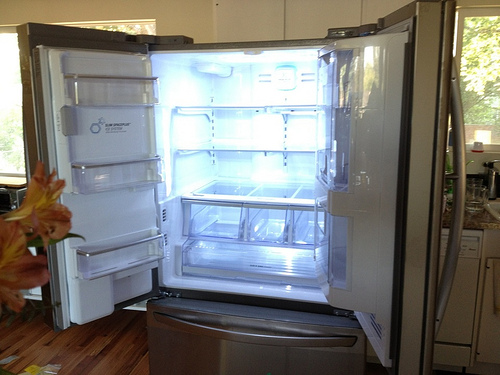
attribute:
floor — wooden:
[1, 308, 145, 374]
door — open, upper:
[15, 21, 165, 331]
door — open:
[314, 0, 466, 375]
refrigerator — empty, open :
[8, 10, 440, 350]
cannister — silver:
[475, 157, 499, 195]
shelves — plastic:
[138, 70, 346, 330]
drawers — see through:
[56, 74, 183, 332]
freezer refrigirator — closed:
[27, 0, 474, 370]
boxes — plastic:
[179, 180, 330, 248]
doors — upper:
[14, 16, 430, 373]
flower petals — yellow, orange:
[15, 162, 67, 311]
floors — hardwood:
[38, 335, 125, 372]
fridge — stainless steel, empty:
[38, 29, 466, 360]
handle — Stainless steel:
[429, 52, 470, 341]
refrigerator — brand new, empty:
[17, 0, 467, 372]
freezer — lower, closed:
[148, 296, 368, 373]